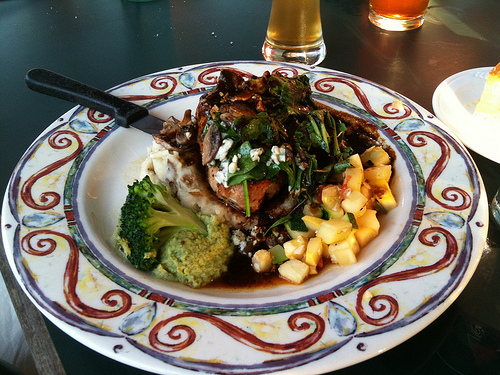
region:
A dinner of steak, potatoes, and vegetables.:
[116, 64, 397, 289]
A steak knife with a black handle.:
[25, 65, 176, 141]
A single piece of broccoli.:
[119, 173, 205, 269]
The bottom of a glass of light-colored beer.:
[262, 0, 324, 67]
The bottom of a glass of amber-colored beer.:
[365, 0, 430, 34]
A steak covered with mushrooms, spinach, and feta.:
[197, 68, 332, 215]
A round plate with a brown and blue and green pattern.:
[1, 58, 491, 374]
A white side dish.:
[430, 63, 499, 165]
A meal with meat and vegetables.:
[116, 65, 400, 291]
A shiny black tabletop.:
[2, 0, 497, 373]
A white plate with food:
[1, 58, 488, 373]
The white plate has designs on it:
[3, 62, 488, 369]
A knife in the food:
[26, 68, 175, 143]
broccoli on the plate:
[118, 180, 241, 278]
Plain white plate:
[432, 63, 497, 170]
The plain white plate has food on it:
[431, 67, 499, 174]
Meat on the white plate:
[188, 70, 342, 204]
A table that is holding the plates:
[6, 5, 491, 370]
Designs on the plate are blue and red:
[0, 56, 485, 371]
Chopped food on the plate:
[258, 154, 426, 286]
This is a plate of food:
[0, 2, 496, 370]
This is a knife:
[22, 47, 184, 154]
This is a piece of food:
[191, 58, 303, 215]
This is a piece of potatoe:
[249, 244, 279, 288]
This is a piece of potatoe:
[273, 258, 312, 284]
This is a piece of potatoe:
[277, 235, 314, 258]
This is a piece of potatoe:
[298, 236, 329, 275]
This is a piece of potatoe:
[327, 240, 363, 267]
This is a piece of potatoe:
[302, 195, 327, 237]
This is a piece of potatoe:
[314, 175, 346, 213]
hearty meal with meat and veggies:
[7, 49, 486, 355]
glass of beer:
[262, 1, 328, 61]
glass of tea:
[364, 0, 429, 35]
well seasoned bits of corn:
[267, 145, 399, 280]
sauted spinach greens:
[219, 83, 342, 188]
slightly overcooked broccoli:
[109, 177, 237, 292]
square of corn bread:
[475, 69, 498, 131]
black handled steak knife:
[27, 63, 154, 140]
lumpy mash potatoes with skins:
[147, 147, 217, 214]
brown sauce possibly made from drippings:
[222, 243, 278, 298]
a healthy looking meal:
[1, 30, 486, 372]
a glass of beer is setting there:
[258, 8, 339, 80]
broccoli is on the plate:
[111, 169, 228, 299]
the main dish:
[196, 68, 368, 218]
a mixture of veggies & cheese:
[201, 101, 361, 225]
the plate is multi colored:
[1, 106, 163, 346]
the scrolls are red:
[327, 74, 459, 341]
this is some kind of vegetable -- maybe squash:
[243, 137, 414, 278]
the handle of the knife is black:
[26, 63, 149, 158]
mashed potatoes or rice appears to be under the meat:
[153, 120, 203, 220]